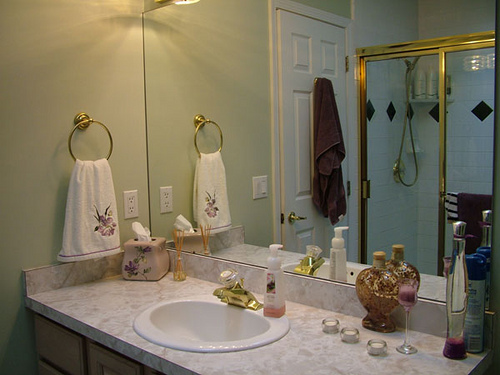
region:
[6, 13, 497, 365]
a scene inside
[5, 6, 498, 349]
an image of a bathroom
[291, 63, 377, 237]
a towel on a door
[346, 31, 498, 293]
a shower in the background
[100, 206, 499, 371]
some items on the bathroom counter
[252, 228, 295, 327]
a soap bottle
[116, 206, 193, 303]
a toilet paper dispenser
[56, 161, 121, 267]
a towel in holder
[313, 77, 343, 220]
a towel on a door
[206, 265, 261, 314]
a brass faucet on a sink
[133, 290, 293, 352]
a white sink in a bathroom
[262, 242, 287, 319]
hand soap in a bottle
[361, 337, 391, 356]
a candle in glass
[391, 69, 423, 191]
a shower hose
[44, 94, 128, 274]
hand towel on a broze holder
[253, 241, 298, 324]
hand soap in a plastic bottle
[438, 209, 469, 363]
long bottle of perfume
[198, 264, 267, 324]
white and gold fauce fixture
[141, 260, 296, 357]
white sink with gold fixture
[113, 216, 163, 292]
floral tissue box container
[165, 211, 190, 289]
aroma oil with sticks sticking out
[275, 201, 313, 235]
door handle on a white door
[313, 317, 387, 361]
row of small candles on a counter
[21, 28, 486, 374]
a photo in a bathroom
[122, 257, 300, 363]
a white sink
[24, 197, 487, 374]
some items on the counter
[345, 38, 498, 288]
a shower that is gold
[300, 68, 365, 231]
a purple towel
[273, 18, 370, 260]
a white door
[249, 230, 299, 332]
a soap bottle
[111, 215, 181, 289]
a dispenser for paper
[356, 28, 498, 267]
Gold colored frame on shower door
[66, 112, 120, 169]
Gold colored towel rack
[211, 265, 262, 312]
Gold bathroom faucet with clear handle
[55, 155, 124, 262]
White towel with purple flower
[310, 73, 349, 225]
Towel hanging on back of door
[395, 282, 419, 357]
Tall glass with a candle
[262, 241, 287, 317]
Almost empty bottle of soap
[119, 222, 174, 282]
Kleenex box with a purple flower on it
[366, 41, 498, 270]
Double glass shower door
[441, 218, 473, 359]
Tall decorative bottle